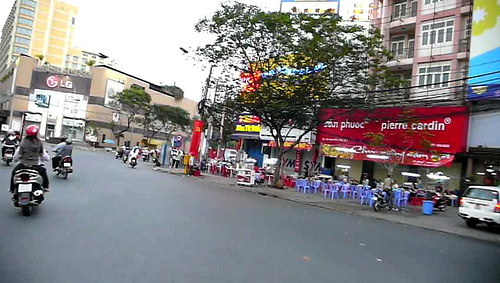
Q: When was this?
A: Day time.